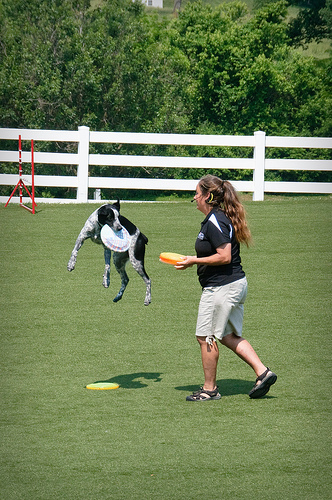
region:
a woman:
[174, 173, 279, 403]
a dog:
[63, 198, 156, 308]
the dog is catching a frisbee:
[62, 197, 155, 307]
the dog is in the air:
[65, 199, 155, 307]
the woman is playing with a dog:
[67, 171, 280, 401]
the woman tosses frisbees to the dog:
[62, 174, 290, 402]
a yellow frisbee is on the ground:
[84, 378, 120, 393]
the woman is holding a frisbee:
[157, 170, 288, 401]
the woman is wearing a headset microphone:
[158, 171, 285, 401]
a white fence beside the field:
[2, 123, 329, 201]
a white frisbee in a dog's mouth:
[97, 219, 133, 256]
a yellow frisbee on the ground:
[82, 378, 124, 393]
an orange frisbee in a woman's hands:
[154, 240, 190, 266]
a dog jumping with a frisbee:
[62, 193, 162, 314]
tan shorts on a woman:
[190, 266, 257, 346]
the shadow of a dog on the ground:
[89, 361, 163, 394]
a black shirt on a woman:
[195, 206, 244, 290]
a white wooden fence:
[0, 123, 331, 201]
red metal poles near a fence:
[4, 120, 52, 225]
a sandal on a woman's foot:
[175, 383, 226, 403]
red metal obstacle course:
[6, 131, 39, 215]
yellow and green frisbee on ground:
[84, 378, 118, 392]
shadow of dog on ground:
[94, 364, 163, 392]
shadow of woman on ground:
[173, 373, 260, 400]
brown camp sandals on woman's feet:
[174, 361, 280, 403]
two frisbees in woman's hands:
[156, 247, 188, 267]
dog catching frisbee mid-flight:
[58, 195, 155, 313]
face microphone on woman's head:
[188, 189, 208, 204]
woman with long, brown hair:
[158, 164, 285, 416]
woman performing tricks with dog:
[156, 166, 281, 407]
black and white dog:
[70, 199, 152, 308]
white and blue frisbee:
[99, 221, 131, 255]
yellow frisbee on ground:
[84, 381, 119, 393]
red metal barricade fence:
[0, 136, 40, 217]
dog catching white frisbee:
[67, 200, 154, 305]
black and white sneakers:
[182, 371, 280, 402]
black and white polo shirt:
[194, 210, 245, 283]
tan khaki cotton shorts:
[197, 278, 251, 338]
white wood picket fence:
[1, 126, 328, 212]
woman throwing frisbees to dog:
[166, 174, 275, 401]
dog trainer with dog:
[170, 148, 280, 407]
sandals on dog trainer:
[177, 382, 232, 402]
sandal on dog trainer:
[247, 368, 281, 401]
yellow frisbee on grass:
[78, 369, 138, 397]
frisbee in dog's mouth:
[89, 222, 135, 260]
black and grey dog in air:
[66, 195, 158, 307]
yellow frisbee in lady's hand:
[155, 247, 197, 269]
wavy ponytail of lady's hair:
[193, 174, 257, 247]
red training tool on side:
[2, 134, 50, 219]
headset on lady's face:
[180, 193, 211, 202]